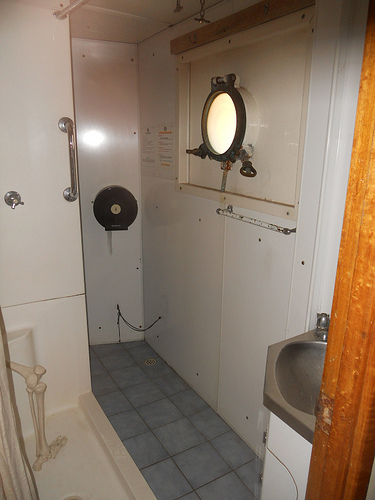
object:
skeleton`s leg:
[33, 382, 47, 456]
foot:
[32, 435, 68, 470]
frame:
[185, 75, 260, 178]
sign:
[141, 126, 156, 164]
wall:
[136, 2, 368, 460]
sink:
[275, 340, 327, 412]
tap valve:
[4, 188, 25, 209]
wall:
[0, 0, 91, 411]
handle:
[57, 116, 78, 202]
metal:
[73, 162, 76, 188]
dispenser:
[94, 183, 138, 232]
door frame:
[307, 1, 374, 499]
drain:
[143, 355, 158, 367]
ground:
[88, 339, 262, 500]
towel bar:
[215, 200, 297, 238]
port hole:
[202, 90, 237, 155]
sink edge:
[261, 345, 278, 415]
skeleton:
[8, 355, 70, 475]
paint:
[256, 222, 268, 224]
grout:
[174, 417, 221, 441]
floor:
[89, 340, 264, 498]